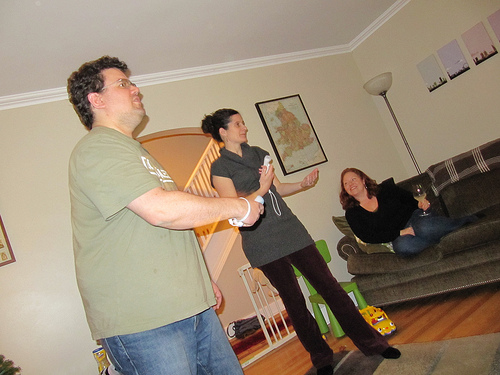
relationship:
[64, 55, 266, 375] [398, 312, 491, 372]
man standing in floor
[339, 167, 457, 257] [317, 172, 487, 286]
person sitting in couch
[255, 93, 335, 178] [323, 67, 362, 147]
frame hanging on wall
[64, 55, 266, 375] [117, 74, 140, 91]
man wearing specs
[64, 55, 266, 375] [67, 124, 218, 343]
man wearing green color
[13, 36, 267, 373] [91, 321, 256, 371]
man wearing jeans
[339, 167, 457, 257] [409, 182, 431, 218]
person holding glass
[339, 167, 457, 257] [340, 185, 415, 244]
person wearing shirt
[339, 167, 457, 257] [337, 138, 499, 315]
person on couch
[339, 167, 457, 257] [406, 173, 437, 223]
person holding glass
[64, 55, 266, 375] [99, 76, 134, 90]
man wearing glasses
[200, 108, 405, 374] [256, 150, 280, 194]
person playing games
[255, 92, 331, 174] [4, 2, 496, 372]
picture on wall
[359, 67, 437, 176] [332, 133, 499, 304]
lamp behind couch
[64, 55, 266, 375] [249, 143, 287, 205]
man playing wii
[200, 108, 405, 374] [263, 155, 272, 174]
person playing controllers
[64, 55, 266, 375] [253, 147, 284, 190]
man playing wii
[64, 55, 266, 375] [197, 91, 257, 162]
man and a woman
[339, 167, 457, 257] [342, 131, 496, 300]
person on couch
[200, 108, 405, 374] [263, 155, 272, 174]
person holding controllers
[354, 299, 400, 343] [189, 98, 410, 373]
toy behind woman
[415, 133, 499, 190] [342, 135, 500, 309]
blanket on couch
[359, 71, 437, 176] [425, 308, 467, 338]
lamp on floor